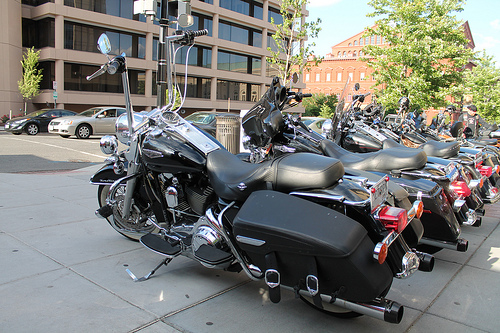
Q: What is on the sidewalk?
A: Motorcycles.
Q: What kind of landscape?
A: City.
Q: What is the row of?
A: Motorcycles.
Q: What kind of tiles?
A: Square.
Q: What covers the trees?
A: Leaves.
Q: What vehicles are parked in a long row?
A: Motorcycles.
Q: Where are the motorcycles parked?
A: On sidewalk.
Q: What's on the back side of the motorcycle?
A: Saddlebag.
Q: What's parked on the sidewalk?
A: Motorcycles.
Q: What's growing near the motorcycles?
A: Trees.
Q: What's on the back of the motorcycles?
A: Tail lights.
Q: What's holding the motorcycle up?
A: Kick stand.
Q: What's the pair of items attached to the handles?
A: Mirrors.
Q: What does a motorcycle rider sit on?
A: The seat.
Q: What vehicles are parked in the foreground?
A: Motorcycles.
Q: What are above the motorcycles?
A: Trees.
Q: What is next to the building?
A: A small tree.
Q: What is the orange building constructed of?
A: Brick.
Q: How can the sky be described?
A: Blue and clear.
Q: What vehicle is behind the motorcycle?
A: A car.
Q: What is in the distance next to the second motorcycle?
A: A trash bin.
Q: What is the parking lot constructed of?
A: Concrete.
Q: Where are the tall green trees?
A: Above the motorcycles.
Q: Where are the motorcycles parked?
A: Sidewalk.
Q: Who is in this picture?
A: No one.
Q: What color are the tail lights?
A: Red.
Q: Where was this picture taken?
A: Daytime.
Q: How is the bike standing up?
A: Kickstand.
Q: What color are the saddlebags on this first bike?
A: Black.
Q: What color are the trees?
A: Green.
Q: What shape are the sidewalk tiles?
A: Square.